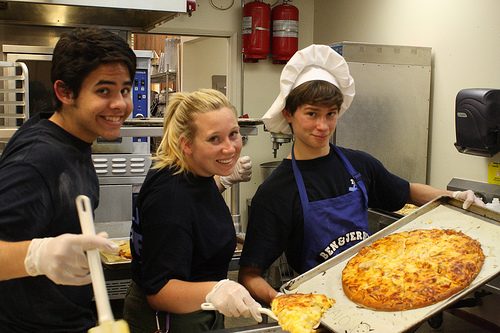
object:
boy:
[235, 75, 485, 305]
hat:
[259, 42, 357, 136]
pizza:
[339, 227, 486, 312]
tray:
[276, 193, 499, 333]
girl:
[121, 86, 264, 332]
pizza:
[268, 291, 337, 333]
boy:
[0, 22, 138, 332]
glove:
[22, 229, 120, 287]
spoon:
[72, 193, 133, 331]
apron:
[289, 141, 372, 269]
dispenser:
[452, 87, 500, 158]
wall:
[155, 0, 499, 233]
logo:
[316, 229, 370, 259]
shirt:
[128, 160, 238, 296]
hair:
[143, 86, 239, 178]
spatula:
[198, 301, 323, 329]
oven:
[0, 42, 153, 184]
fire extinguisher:
[269, 0, 300, 65]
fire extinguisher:
[239, 0, 271, 64]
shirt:
[1, 110, 102, 332]